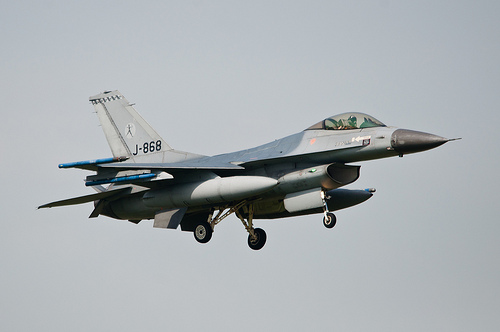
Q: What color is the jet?
A: Grey.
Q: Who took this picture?
A: A photographer.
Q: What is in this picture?
A: A jet.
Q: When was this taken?
A: Daytime.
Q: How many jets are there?
A: One.